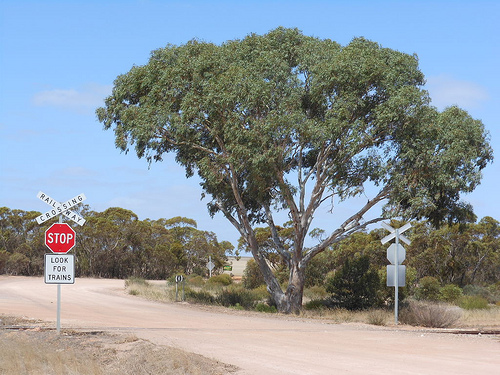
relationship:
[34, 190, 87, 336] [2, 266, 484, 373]
sign on left side of road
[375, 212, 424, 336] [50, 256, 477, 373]
signs on right side of road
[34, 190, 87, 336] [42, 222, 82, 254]
sign under stop sign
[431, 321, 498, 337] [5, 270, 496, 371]
shadow on ground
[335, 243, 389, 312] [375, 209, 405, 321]
bush behind sign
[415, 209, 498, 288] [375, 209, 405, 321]
bush behind sign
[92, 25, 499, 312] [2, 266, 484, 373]
tree on side of road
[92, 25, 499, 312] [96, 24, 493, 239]
tree has foliage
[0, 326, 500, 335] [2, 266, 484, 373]
railroad by road